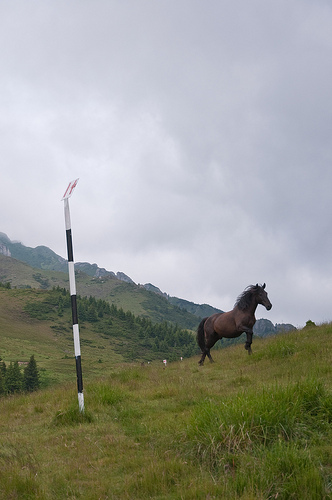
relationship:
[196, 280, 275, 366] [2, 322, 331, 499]
horse on hill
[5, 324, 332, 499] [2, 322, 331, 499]
grass on hill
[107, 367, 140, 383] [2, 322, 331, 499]
grass on hill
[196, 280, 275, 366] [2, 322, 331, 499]
horse going up hill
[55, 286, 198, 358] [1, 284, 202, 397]
trees on hill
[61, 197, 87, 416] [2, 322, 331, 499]
pole on hill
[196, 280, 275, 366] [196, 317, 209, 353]
horse has tail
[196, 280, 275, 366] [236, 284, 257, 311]
horse has mane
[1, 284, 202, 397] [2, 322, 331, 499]
hill behind hill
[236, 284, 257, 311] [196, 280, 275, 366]
mane on horse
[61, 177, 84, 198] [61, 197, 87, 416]
marker on pole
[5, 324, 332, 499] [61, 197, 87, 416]
grass around pole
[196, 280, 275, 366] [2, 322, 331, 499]
horse climbing hill